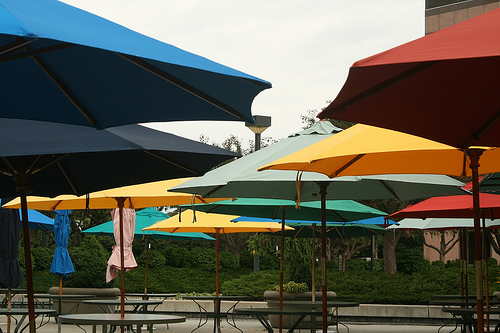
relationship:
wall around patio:
[139, 299, 496, 321] [41, 313, 481, 332]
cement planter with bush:
[51, 285, 118, 315] [70, 225, 109, 287]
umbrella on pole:
[103, 205, 139, 283] [116, 197, 126, 317]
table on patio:
[54, 299, 193, 331] [8, 291, 490, 331]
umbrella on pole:
[137, 197, 296, 238] [207, 220, 221, 331]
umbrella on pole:
[208, 191, 378, 223] [271, 208, 291, 291]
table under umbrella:
[27, 289, 118, 303] [10, 114, 242, 199]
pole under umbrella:
[216, 228, 221, 317] [143, 210, 293, 230]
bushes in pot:
[274, 274, 313, 296] [263, 280, 327, 331]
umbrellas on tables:
[43, 207, 143, 276] [59, 295, 193, 330]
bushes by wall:
[0, 205, 500, 306] [157, 258, 466, 299]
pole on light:
[466, 154, 490, 326] [246, 114, 271, 136]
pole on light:
[310, 179, 336, 329] [246, 114, 271, 136]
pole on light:
[204, 228, 227, 330] [246, 114, 271, 136]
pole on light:
[456, 238, 473, 320] [246, 114, 271, 136]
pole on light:
[9, 177, 46, 331] [246, 114, 271, 136]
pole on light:
[108, 200, 135, 331] [246, 114, 271, 136]